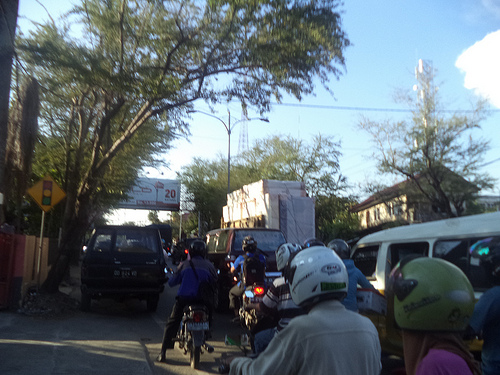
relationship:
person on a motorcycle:
[172, 234, 218, 311] [169, 292, 226, 370]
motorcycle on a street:
[169, 292, 226, 370] [195, 289, 252, 373]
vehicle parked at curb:
[86, 222, 165, 310] [160, 292, 221, 373]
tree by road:
[0, 0, 354, 295] [145, 253, 205, 360]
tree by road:
[2, 2, 349, 302] [145, 253, 205, 360]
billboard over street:
[113, 171, 183, 206] [159, 294, 172, 316]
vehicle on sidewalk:
[80, 225, 168, 312] [0, 302, 177, 368]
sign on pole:
[26, 170, 67, 212] [32, 211, 47, 283]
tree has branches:
[350, 51, 498, 230] [399, 133, 461, 178]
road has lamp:
[0, 248, 249, 375] [256, 109, 272, 124]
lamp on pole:
[256, 109, 272, 124] [223, 144, 236, 177]